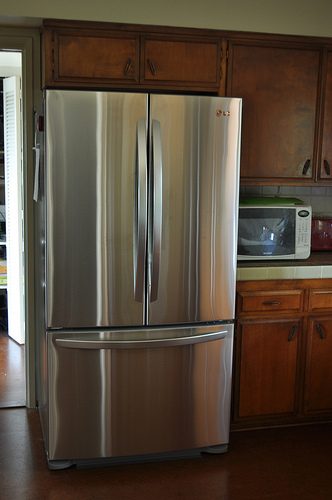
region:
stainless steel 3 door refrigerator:
[44, 89, 253, 475]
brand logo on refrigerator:
[210, 106, 232, 119]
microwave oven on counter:
[236, 200, 315, 264]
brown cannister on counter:
[316, 213, 329, 256]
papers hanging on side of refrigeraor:
[30, 115, 42, 213]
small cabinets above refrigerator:
[53, 25, 226, 89]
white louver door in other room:
[5, 71, 21, 345]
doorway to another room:
[3, 30, 36, 411]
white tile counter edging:
[239, 264, 330, 282]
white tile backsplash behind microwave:
[243, 187, 330, 215]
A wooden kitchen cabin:
[238, 282, 309, 425]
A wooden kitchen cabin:
[304, 291, 326, 426]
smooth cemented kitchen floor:
[241, 436, 312, 495]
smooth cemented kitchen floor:
[101, 463, 179, 492]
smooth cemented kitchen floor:
[5, 408, 45, 494]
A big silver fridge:
[36, 88, 251, 409]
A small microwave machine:
[239, 200, 308, 257]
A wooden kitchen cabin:
[52, 26, 136, 81]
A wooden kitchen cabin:
[136, 25, 219, 92]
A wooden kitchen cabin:
[229, 39, 331, 177]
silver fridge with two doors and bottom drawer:
[37, 88, 241, 454]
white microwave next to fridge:
[238, 198, 318, 266]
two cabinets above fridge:
[37, 18, 225, 93]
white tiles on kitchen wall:
[241, 181, 331, 216]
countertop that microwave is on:
[237, 263, 331, 279]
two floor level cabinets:
[239, 283, 330, 428]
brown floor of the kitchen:
[4, 407, 331, 499]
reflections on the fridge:
[79, 98, 235, 446]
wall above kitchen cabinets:
[9, 4, 330, 33]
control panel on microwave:
[295, 217, 312, 249]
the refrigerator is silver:
[4, 76, 253, 463]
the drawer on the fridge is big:
[11, 311, 253, 485]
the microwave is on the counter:
[213, 185, 317, 277]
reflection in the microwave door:
[230, 211, 295, 266]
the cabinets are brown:
[211, 282, 322, 450]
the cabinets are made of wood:
[225, 284, 315, 439]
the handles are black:
[273, 319, 331, 341]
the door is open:
[0, 35, 46, 357]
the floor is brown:
[222, 433, 322, 487]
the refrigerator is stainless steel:
[18, 63, 249, 407]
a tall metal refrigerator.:
[34, 85, 255, 469]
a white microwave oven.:
[234, 189, 318, 278]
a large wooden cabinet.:
[228, 35, 318, 177]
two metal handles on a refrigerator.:
[117, 113, 179, 306]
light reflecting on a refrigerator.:
[85, 85, 119, 330]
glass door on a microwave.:
[235, 209, 296, 263]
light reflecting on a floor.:
[0, 408, 27, 499]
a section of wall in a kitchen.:
[0, 1, 329, 41]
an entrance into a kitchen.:
[0, 74, 31, 344]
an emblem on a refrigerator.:
[211, 92, 234, 132]